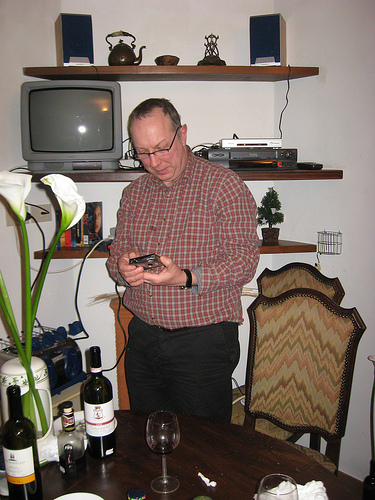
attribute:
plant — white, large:
[1, 165, 87, 441]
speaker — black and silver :
[248, 12, 287, 68]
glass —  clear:
[142, 406, 183, 496]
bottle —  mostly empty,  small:
[56, 400, 88, 490]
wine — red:
[73, 341, 138, 464]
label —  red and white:
[82, 400, 115, 438]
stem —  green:
[22, 269, 33, 335]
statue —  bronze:
[194, 30, 230, 70]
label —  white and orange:
[3, 444, 37, 487]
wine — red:
[133, 409, 205, 497]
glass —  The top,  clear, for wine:
[251, 470, 300, 499]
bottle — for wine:
[81, 345, 115, 459]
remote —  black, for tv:
[298, 159, 324, 172]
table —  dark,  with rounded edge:
[25, 370, 357, 499]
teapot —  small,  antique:
[105, 29, 145, 65]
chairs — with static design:
[244, 262, 369, 475]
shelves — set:
[11, 63, 344, 259]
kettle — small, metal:
[103, 27, 148, 67]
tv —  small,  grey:
[26, 82, 121, 173]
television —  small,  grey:
[21, 80, 123, 175]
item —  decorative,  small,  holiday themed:
[247, 182, 290, 243]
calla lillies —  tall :
[2, 169, 89, 436]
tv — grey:
[20, 77, 128, 172]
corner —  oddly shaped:
[46, 0, 287, 15]